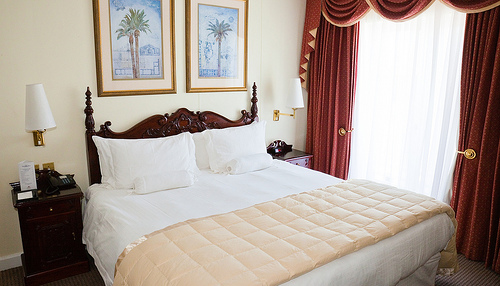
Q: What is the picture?
A: Bedroom.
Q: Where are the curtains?
A: Over the window.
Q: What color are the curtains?
A: Red.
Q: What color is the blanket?
A: Tan.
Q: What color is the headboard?
A: Brown.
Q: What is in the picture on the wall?
A: Palm trees.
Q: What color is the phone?
A: Black.